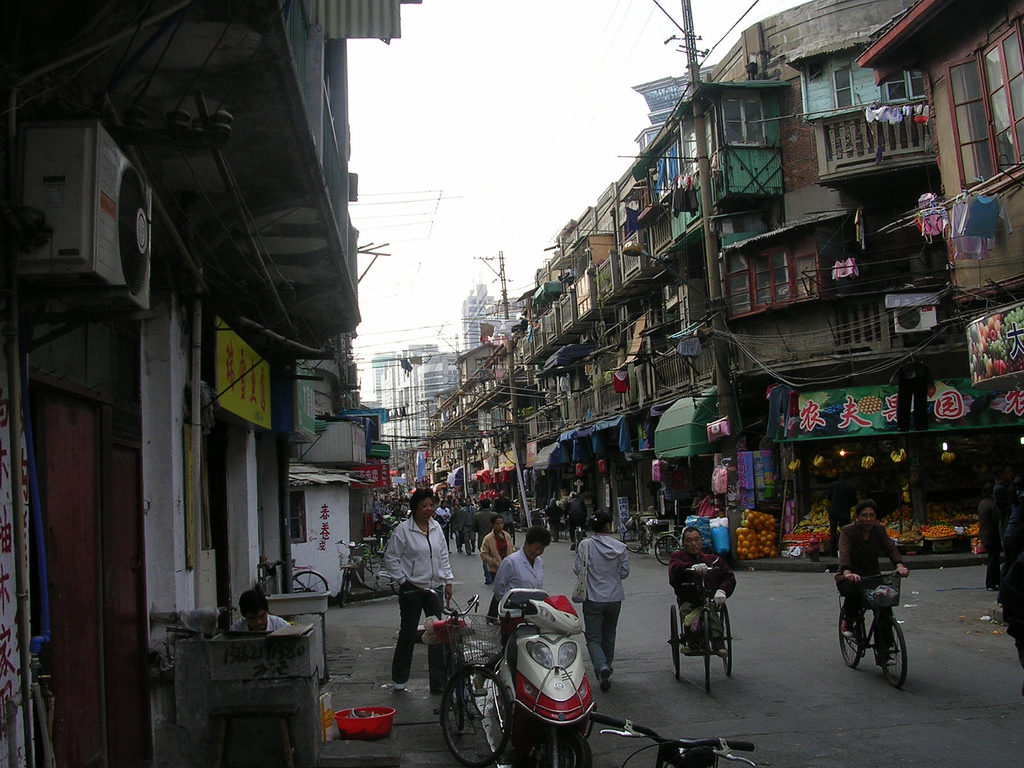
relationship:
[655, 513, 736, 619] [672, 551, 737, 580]
man in sweatshirt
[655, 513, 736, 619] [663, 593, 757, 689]
man pedalling cart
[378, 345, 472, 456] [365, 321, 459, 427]
wall on building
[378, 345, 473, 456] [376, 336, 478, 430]
wall on building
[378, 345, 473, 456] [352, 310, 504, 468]
wall on building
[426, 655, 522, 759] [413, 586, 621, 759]
tire of a bike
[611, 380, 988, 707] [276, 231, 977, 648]
people are riding bikes in street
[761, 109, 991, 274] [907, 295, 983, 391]
clothes drying outside of window